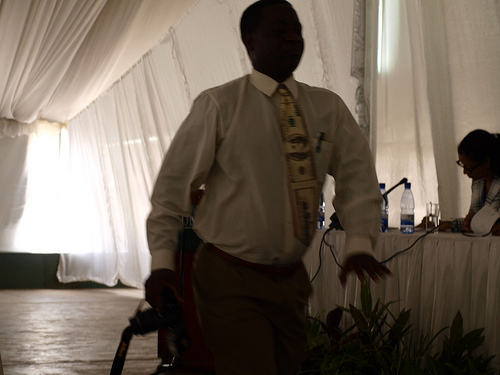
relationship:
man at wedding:
[145, 1, 391, 374] [0, 2, 499, 373]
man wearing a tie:
[145, 1, 391, 374] [269, 84, 319, 246]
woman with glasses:
[415, 129, 499, 235] [456, 159, 479, 170]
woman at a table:
[415, 129, 499, 235] [303, 226, 499, 359]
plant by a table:
[342, 294, 397, 375] [303, 226, 499, 359]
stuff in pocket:
[316, 131, 327, 153] [308, 139, 333, 178]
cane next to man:
[111, 296, 178, 374] [145, 1, 391, 374]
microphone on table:
[382, 176, 410, 197] [303, 226, 499, 359]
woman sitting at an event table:
[415, 129, 499, 235] [303, 226, 499, 359]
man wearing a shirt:
[145, 1, 391, 374] [147, 70, 383, 274]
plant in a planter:
[342, 294, 397, 375] [347, 332, 379, 367]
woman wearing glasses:
[415, 129, 499, 235] [456, 159, 479, 170]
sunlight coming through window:
[70, 137, 128, 256] [10, 121, 63, 254]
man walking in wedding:
[145, 1, 391, 374] [0, 2, 499, 373]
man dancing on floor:
[145, 1, 391, 374] [0, 286, 163, 374]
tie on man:
[269, 84, 319, 246] [145, 1, 391, 374]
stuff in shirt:
[316, 131, 327, 153] [147, 70, 383, 274]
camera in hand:
[132, 295, 178, 336] [145, 270, 179, 310]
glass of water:
[425, 203, 438, 230] [428, 215, 436, 230]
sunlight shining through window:
[70, 137, 128, 256] [10, 121, 63, 254]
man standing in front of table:
[145, 1, 391, 374] [303, 226, 499, 359]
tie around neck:
[269, 84, 319, 246] [251, 67, 296, 85]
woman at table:
[415, 129, 499, 235] [303, 226, 499, 359]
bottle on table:
[401, 183, 414, 233] [303, 226, 499, 359]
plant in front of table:
[342, 294, 397, 375] [303, 226, 499, 359]